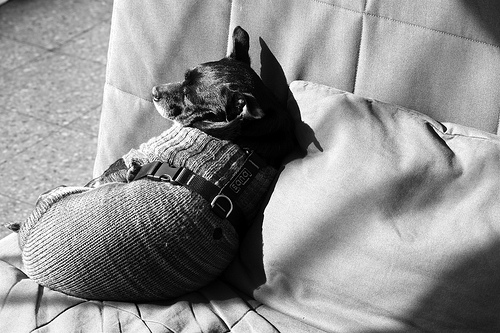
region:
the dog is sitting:
[26, 47, 312, 302]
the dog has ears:
[123, 27, 298, 161]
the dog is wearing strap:
[107, 152, 267, 244]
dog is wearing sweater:
[20, 104, 279, 306]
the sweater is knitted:
[21, 127, 292, 267]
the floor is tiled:
[11, 64, 95, 184]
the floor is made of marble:
[12, 67, 80, 191]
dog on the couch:
[29, 30, 316, 322]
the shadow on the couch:
[254, 38, 349, 193]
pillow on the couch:
[285, 68, 484, 303]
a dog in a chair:
[14, 25, 280, 293]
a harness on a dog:
[121, 117, 291, 233]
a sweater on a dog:
[18, 121, 280, 309]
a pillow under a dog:
[233, 73, 494, 327]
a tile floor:
[1, 2, 108, 232]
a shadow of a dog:
[248, 35, 318, 159]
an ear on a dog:
[230, 24, 250, 66]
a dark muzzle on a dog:
[149, 78, 187, 119]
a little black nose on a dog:
[150, 86, 160, 102]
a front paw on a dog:
[90, 153, 136, 186]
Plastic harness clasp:
[145, 157, 191, 189]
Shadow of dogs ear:
[251, 30, 296, 85]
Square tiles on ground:
[5, 0, 100, 177]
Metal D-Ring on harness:
[205, 185, 231, 220]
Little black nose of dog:
[145, 77, 165, 103]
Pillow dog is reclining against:
[253, 69, 496, 331]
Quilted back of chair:
[98, 2, 498, 231]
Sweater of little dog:
[15, 123, 259, 303]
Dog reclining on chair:
[0, 23, 312, 306]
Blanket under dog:
[1, 234, 318, 329]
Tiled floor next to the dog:
[0, 0, 125, 240]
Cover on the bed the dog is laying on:
[0, 232, 324, 331]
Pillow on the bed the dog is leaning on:
[261, 79, 498, 331]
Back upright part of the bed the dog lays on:
[93, 0, 498, 177]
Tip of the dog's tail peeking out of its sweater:
[6, 220, 21, 231]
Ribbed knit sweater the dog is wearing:
[18, 122, 281, 301]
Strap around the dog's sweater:
[128, 151, 258, 238]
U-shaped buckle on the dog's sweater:
[210, 191, 235, 216]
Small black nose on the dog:
[151, 84, 162, 103]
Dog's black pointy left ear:
[256, 31, 284, 76]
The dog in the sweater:
[6, 26, 267, 311]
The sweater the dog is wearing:
[14, 125, 272, 306]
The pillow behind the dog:
[245, 79, 497, 330]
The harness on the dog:
[128, 147, 272, 239]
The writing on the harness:
[229, 164, 252, 197]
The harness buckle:
[145, 158, 186, 188]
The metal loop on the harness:
[209, 188, 235, 219]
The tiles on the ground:
[2, 0, 114, 250]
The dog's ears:
[227, 23, 264, 125]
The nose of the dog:
[150, 83, 160, 105]